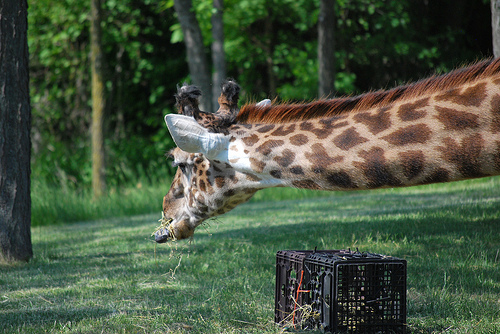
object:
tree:
[80, 2, 111, 206]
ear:
[162, 112, 227, 159]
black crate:
[272, 245, 407, 331]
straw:
[273, 302, 326, 332]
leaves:
[224, 2, 269, 25]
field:
[3, 174, 498, 332]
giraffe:
[148, 56, 500, 242]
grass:
[41, 250, 273, 330]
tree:
[206, 0, 237, 128]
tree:
[314, 2, 340, 100]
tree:
[438, 0, 498, 71]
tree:
[3, 0, 43, 267]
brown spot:
[331, 125, 370, 152]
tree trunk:
[0, 0, 30, 265]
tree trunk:
[85, 0, 105, 200]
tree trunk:
[173, 0, 212, 115]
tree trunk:
[213, 0, 226, 112]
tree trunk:
[317, 0, 335, 99]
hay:
[150, 211, 177, 243]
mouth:
[161, 214, 194, 240]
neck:
[249, 64, 497, 192]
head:
[145, 72, 248, 242]